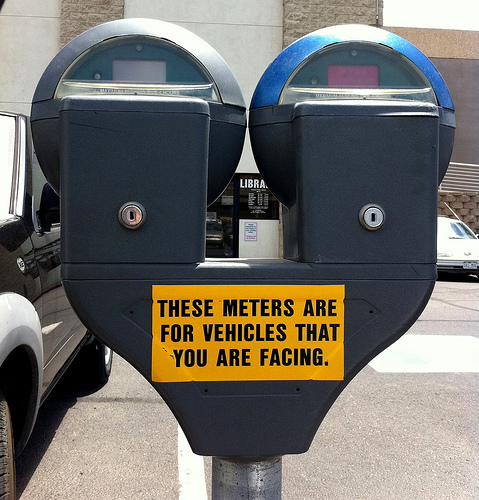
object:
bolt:
[356, 201, 388, 233]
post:
[210, 456, 283, 500]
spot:
[260, 478, 264, 482]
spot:
[235, 482, 238, 486]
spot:
[219, 463, 223, 468]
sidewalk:
[13, 274, 477, 497]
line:
[176, 427, 208, 500]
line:
[365, 333, 479, 375]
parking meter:
[28, 17, 458, 461]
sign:
[152, 284, 345, 382]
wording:
[158, 301, 340, 367]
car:
[436, 214, 478, 277]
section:
[437, 239, 470, 259]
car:
[1, 108, 113, 500]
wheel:
[83, 335, 113, 381]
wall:
[281, 1, 384, 54]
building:
[2, 2, 479, 259]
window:
[206, 173, 236, 259]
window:
[238, 176, 280, 220]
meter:
[29, 17, 247, 262]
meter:
[247, 23, 457, 261]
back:
[283, 99, 439, 263]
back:
[60, 95, 207, 264]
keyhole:
[128, 210, 136, 222]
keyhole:
[369, 212, 377, 222]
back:
[61, 260, 438, 457]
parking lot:
[2, 0, 478, 499]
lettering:
[240, 177, 268, 214]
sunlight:
[195, 257, 250, 269]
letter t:
[157, 299, 168, 317]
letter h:
[168, 299, 179, 317]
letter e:
[181, 299, 190, 317]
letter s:
[191, 297, 203, 318]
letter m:
[223, 299, 237, 317]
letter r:
[271, 298, 282, 316]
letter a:
[303, 299, 315, 316]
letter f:
[160, 324, 169, 342]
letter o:
[171, 323, 182, 343]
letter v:
[202, 323, 213, 341]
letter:
[240, 178, 245, 188]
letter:
[248, 179, 253, 189]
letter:
[254, 179, 260, 188]